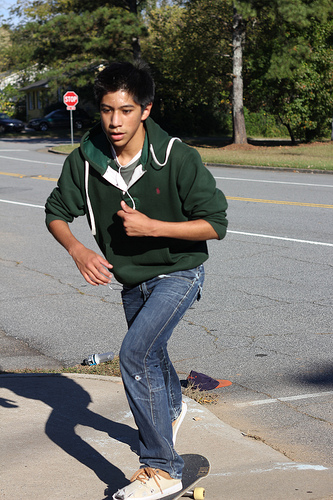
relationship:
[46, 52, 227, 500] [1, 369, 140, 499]
boy casting shadow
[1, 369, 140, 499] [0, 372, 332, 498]
shadow on sidewalk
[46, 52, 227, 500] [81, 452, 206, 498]
boy on skateboard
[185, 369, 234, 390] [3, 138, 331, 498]
cap on ground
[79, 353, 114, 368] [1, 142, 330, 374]
bottle on street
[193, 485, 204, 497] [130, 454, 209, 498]
wheels on skateboard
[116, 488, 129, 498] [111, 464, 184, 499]
hole in shoe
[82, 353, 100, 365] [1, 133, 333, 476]
bottle on driveway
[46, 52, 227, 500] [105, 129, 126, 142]
boy has mouth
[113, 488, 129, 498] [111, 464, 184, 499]
hole in shoe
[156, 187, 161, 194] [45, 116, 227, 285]
emblem on hoodie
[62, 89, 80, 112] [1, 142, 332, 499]
stop sign near road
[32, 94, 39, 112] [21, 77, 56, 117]
shutter on house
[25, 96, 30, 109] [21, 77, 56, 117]
shutter on house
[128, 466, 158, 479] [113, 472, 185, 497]
laces are on shoe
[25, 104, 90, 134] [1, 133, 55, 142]
car in driveway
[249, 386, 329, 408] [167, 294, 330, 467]
line on pavement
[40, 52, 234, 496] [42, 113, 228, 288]
boy wearing hoodie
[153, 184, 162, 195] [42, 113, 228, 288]
emblem on hoodie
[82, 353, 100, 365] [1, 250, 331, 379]
bottle in street